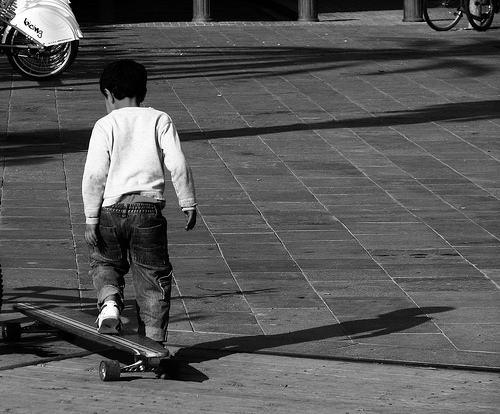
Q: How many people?
A: One.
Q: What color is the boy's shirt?
A: White.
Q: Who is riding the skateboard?
A: Boy.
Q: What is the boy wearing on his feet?
A: Sneakers.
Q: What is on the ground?
A: Stones.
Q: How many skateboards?
A: One.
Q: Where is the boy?
A: On the sidewalk.